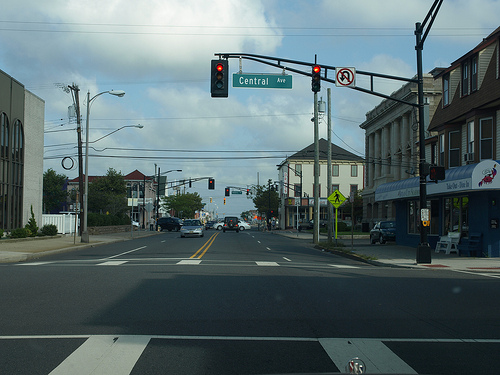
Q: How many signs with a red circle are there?
A: 1.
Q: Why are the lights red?
A: Stop traffic.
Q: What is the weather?
A: Slightly cloudy and sunny.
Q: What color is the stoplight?
A: Red.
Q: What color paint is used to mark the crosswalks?
A: White.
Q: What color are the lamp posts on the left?
A: White.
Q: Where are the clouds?
A: In the sky.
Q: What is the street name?
A: Central Ave.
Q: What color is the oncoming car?
A: Silver.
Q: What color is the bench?
A: White.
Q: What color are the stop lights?
A: Red.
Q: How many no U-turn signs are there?
A: One.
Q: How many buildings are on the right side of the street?
A: Three.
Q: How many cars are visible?
A: Six.